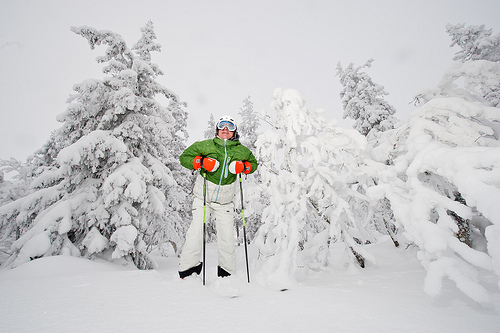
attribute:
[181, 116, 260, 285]
man — skier, skiing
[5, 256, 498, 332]
snow — white, deep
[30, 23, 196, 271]
tree — tall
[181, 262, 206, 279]
shoe — black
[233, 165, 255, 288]
ski pole — black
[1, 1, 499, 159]
sky — gray, white, overcast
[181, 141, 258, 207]
jacket — white, green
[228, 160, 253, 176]
glove — orange, white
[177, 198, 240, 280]
pants — white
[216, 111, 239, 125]
helmet — white